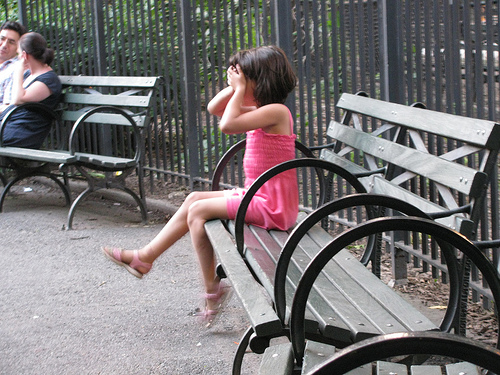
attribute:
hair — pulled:
[17, 26, 56, 64]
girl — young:
[175, 60, 310, 280]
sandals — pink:
[96, 232, 251, 331]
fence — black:
[107, 4, 209, 200]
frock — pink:
[224, 102, 299, 231]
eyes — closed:
[220, 63, 256, 93]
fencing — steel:
[23, 5, 497, 308]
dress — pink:
[227, 112, 297, 220]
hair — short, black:
[227, 44, 297, 109]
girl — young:
[99, 33, 305, 331]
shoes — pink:
[94, 229, 237, 334]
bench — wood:
[199, 92, 494, 371]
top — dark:
[4, 66, 65, 150]